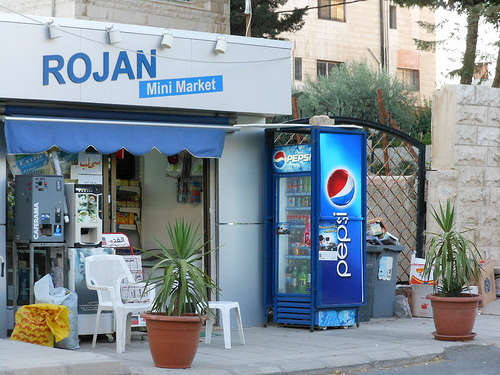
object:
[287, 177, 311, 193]
soda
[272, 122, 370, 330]
cooler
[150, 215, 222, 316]
plant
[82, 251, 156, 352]
stool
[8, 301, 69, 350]
bag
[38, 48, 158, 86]
rojan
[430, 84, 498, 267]
wall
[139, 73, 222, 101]
sign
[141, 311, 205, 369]
pot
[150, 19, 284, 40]
roof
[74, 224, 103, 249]
dispenser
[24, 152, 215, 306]
store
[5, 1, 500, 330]
building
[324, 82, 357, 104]
bush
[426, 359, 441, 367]
leaves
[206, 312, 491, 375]
ground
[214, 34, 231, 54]
light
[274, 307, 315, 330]
vent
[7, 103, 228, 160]
awning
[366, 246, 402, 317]
trash can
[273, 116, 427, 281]
door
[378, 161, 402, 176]
trunk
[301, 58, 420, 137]
tree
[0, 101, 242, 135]
shelves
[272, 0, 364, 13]
line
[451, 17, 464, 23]
sky